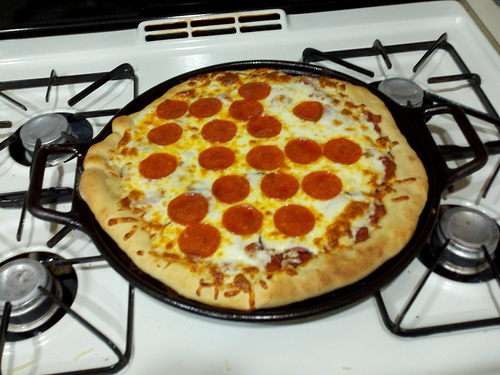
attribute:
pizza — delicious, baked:
[77, 60, 427, 308]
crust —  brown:
[80, 67, 429, 312]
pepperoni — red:
[243, 144, 288, 176]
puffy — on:
[81, 143, 106, 211]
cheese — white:
[150, 180, 186, 196]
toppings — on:
[198, 113, 288, 171]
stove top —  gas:
[0, 0, 496, 372]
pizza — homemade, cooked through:
[77, 57, 443, 328]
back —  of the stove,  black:
[2, 0, 140, 29]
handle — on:
[415, 86, 482, 187]